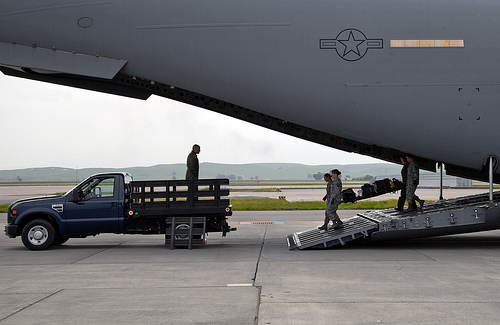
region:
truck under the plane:
[3, 165, 246, 256]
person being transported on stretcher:
[338, 165, 399, 216]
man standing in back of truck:
[180, 138, 202, 203]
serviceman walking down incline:
[324, 162, 344, 224]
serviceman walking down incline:
[322, 173, 329, 233]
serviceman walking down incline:
[401, 159, 420, 210]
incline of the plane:
[286, 225, 368, 246]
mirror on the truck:
[64, 184, 91, 211]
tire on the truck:
[25, 220, 67, 255]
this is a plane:
[367, 119, 389, 136]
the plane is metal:
[320, 102, 380, 162]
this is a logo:
[322, 15, 404, 67]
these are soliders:
[269, 197, 378, 223]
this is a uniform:
[329, 197, 354, 267]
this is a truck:
[49, 205, 89, 243]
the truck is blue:
[21, 158, 81, 218]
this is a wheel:
[34, 228, 45, 239]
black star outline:
[333, 29, 365, 60]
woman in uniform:
[328, 168, 341, 230]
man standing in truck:
[183, 137, 203, 203]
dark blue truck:
[3, 170, 126, 240]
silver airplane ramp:
[277, 209, 486, 246]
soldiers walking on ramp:
[319, 168, 347, 230]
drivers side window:
[80, 176, 118, 201]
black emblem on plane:
[308, 16, 390, 67]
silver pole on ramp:
[483, 154, 496, 208]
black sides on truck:
[130, 181, 229, 209]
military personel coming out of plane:
[311, 147, 441, 224]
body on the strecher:
[341, 174, 408, 201]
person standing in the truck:
[175, 137, 204, 220]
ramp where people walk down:
[292, 216, 377, 240]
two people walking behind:
[389, 157, 436, 222]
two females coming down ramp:
[307, 162, 353, 242]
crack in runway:
[252, 219, 274, 324]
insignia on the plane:
[295, 17, 437, 82]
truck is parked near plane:
[0, 171, 250, 239]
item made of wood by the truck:
[151, 214, 235, 254]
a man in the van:
[179, 124, 228, 229]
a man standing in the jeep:
[173, 128, 223, 238]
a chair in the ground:
[157, 211, 207, 251]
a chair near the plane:
[155, 208, 237, 267]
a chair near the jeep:
[158, 215, 215, 246]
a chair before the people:
[155, 212, 232, 263]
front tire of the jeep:
[16, 208, 66, 250]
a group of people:
[277, 150, 448, 230]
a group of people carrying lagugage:
[291, 150, 442, 242]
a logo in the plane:
[283, 14, 429, 89]